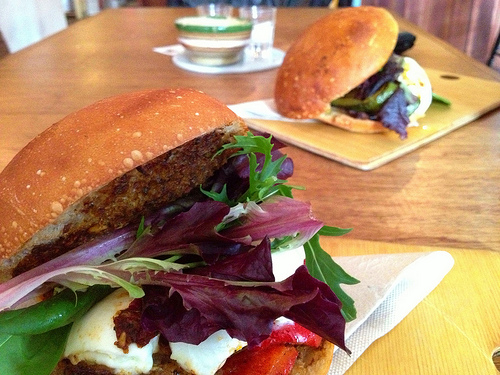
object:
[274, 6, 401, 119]
bun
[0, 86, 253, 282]
bun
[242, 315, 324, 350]
tomato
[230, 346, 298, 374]
tomato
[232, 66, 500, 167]
plate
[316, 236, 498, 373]
plate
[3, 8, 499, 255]
table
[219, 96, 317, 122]
napkin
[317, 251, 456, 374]
napkin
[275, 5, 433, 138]
hamburger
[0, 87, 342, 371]
hamburger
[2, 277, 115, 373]
lettuce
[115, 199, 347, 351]
lettuce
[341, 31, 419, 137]
lettuce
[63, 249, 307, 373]
cheese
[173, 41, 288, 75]
plate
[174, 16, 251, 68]
bowl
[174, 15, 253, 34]
trim